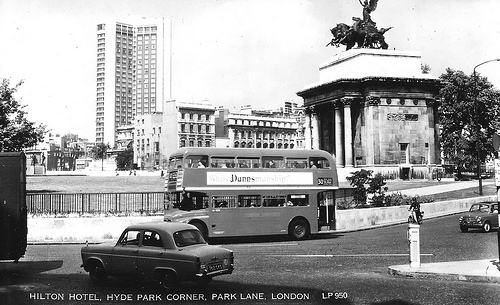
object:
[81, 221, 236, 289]
car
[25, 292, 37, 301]
words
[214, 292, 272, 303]
park lane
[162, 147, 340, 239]
bus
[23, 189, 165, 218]
railings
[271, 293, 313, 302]
london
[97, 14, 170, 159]
building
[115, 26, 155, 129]
windows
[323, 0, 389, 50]
statue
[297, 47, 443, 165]
building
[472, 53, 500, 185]
post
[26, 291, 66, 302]
hilton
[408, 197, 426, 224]
person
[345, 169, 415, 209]
trees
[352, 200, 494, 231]
curb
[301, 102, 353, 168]
pillars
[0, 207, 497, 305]
road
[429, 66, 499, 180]
tree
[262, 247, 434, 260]
line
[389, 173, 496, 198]
sidewalk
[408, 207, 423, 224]
bike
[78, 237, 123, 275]
front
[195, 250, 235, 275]
back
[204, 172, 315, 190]
rectangle